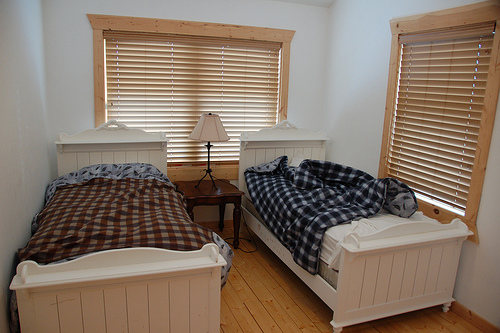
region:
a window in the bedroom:
[396, 29, 482, 225]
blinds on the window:
[96, 25, 280, 160]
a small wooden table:
[181, 180, 231, 211]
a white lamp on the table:
[196, 108, 226, 187]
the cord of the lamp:
[221, 202, 263, 255]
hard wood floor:
[230, 259, 306, 326]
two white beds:
[18, 118, 465, 308]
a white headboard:
[238, 125, 318, 170]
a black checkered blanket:
[253, 147, 395, 249]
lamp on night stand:
[192, 98, 237, 183]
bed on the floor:
[247, 127, 462, 319]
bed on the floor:
[26, 122, 228, 326]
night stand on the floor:
[192, 179, 242, 228]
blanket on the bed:
[281, 155, 380, 225]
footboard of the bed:
[73, 250, 216, 320]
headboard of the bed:
[61, 122, 170, 167]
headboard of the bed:
[239, 120, 330, 157]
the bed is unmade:
[315, 183, 375, 208]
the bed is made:
[98, 183, 137, 222]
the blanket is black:
[303, 184, 329, 206]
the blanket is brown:
[106, 212, 143, 232]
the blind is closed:
[153, 62, 184, 93]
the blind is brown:
[411, 131, 426, 148]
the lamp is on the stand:
[198, 171, 224, 196]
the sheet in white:
[356, 220, 379, 230]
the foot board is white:
[358, 265, 403, 295]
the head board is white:
[98, 137, 130, 158]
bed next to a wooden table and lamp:
[6, 114, 246, 331]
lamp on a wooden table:
[173, 111, 248, 251]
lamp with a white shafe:
[187, 109, 236, 192]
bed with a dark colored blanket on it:
[238, 119, 478, 331]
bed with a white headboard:
[236, 118, 475, 331]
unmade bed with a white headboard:
[237, 112, 477, 332]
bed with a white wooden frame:
[237, 118, 477, 331]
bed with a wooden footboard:
[237, 117, 477, 331]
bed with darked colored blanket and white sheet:
[237, 118, 473, 331]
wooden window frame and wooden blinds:
[376, 1, 499, 246]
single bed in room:
[5, 105, 239, 330]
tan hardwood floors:
[187, 210, 497, 331]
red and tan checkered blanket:
[11, 166, 231, 273]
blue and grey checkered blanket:
[237, 145, 424, 275]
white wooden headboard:
[45, 115, 175, 177]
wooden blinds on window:
[100, 28, 279, 180]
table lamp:
[181, 108, 244, 198]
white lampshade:
[174, 107, 236, 147]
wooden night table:
[171, 175, 256, 247]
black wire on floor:
[216, 230, 260, 256]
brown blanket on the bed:
[45, 170, 206, 257]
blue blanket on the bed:
[248, 157, 415, 274]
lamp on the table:
[175, 105, 230, 195]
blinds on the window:
[97, 32, 292, 165]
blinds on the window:
[383, 27, 485, 212]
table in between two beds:
[182, 170, 242, 245]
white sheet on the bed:
[316, 208, 436, 259]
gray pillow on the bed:
[27, 160, 172, 187]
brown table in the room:
[174, 167, 249, 252]